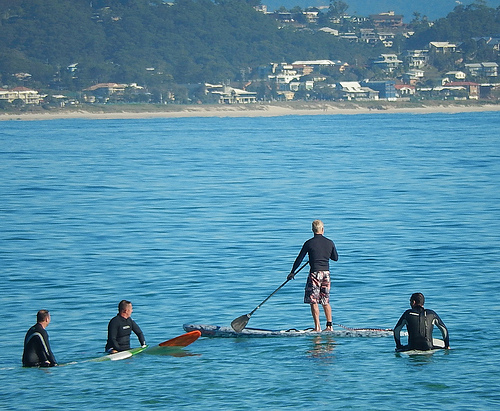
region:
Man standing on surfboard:
[278, 216, 393, 349]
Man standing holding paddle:
[231, 206, 343, 341]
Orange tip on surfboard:
[156, 318, 223, 350]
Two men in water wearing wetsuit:
[18, 295, 145, 371]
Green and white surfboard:
[71, 341, 157, 366]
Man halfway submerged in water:
[393, 285, 465, 377]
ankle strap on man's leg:
[320, 312, 344, 337]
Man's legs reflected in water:
[298, 335, 345, 370]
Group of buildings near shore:
[241, 46, 496, 103]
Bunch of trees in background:
[34, 3, 259, 68]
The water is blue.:
[3, 112, 497, 307]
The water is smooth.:
[4, 115, 497, 340]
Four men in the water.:
[15, 212, 479, 377]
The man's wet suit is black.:
[386, 296, 452, 366]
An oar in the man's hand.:
[226, 246, 312, 342]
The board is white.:
[174, 293, 449, 354]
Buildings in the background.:
[7, 5, 492, 116]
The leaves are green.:
[10, 9, 355, 99]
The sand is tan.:
[3, 87, 498, 133]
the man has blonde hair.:
[307, 212, 324, 239]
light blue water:
[82, 149, 213, 259]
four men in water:
[19, 172, 471, 399]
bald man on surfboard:
[6, 291, 86, 383]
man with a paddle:
[221, 193, 364, 356]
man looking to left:
[378, 270, 461, 369]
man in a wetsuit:
[107, 283, 161, 356]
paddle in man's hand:
[206, 268, 295, 348]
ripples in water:
[36, 163, 160, 239]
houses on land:
[171, 14, 408, 129]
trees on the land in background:
[106, 31, 201, 86]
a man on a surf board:
[126, 137, 438, 398]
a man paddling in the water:
[152, 192, 444, 375]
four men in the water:
[25, 109, 430, 409]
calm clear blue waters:
[40, 130, 252, 296]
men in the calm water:
[3, 132, 438, 409]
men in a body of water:
[19, 124, 496, 404]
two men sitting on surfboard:
[29, 246, 212, 400]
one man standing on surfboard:
[207, 184, 367, 364]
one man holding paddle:
[177, 195, 404, 325]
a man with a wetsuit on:
[379, 273, 492, 380]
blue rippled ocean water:
[117, 157, 342, 220]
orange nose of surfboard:
[158, 318, 224, 360]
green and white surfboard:
[74, 344, 189, 372]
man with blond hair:
[275, 209, 344, 238]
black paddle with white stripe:
[201, 299, 283, 335]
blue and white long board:
[196, 307, 376, 348]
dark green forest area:
[62, 20, 276, 60]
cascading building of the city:
[312, 16, 484, 108]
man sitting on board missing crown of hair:
[22, 286, 64, 373]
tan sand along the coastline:
[184, 109, 452, 114]